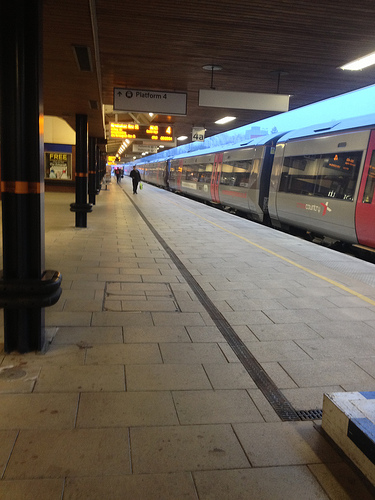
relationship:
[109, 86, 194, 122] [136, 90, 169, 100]
sign indicates platform 4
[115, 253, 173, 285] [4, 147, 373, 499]
bricks make up sidewalk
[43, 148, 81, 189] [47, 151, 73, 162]
poster says free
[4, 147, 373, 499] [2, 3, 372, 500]
sidewalk in subway station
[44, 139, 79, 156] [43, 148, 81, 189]
blue above poster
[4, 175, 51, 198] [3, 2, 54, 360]
ring on pole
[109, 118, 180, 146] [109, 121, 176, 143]
sign indicating sign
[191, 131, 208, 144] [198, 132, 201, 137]
4a on sign black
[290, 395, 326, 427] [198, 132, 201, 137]
drain in sidewalk black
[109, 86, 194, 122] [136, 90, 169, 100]
sign says platform 4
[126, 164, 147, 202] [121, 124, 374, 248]
person waiting for subway train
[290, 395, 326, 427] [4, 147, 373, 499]
drain in sidewalk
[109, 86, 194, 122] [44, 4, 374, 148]
sign hanging from ceiling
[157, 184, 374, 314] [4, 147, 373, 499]
yellow line on sidewalk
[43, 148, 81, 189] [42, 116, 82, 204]
poster on wall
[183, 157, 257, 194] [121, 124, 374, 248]
windows in subway train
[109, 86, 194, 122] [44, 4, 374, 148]
sign hangs down from ceiling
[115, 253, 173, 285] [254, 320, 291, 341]
bricks are made from cement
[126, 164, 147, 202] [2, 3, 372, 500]
person in subway station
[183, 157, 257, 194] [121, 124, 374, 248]
windows on subway train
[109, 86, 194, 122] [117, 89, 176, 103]
sign has writting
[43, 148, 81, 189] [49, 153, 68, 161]
poster has free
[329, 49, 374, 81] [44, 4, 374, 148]
light in ceiling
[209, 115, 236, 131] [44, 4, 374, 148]
light in ceiling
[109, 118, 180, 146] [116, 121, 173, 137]
sign has lit up writting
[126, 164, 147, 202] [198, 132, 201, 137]
person dressed in black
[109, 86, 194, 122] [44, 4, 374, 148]
sign hangs from ceiling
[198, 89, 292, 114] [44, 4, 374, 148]
sign hanging down from ceiling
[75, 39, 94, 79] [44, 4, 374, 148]
vent in ceiling